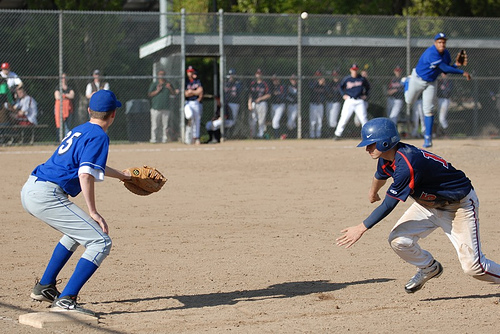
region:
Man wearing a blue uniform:
[19, 85, 167, 317]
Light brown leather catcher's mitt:
[122, 163, 165, 198]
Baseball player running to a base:
[331, 112, 498, 294]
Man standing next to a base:
[17, 87, 168, 314]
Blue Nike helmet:
[354, 115, 401, 152]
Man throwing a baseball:
[399, 32, 473, 147]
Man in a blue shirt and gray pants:
[402, 30, 472, 149]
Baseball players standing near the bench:
[178, 55, 411, 142]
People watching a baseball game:
[0, 58, 176, 141]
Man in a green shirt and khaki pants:
[145, 68, 177, 145]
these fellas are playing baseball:
[32, 0, 494, 330]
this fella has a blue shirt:
[13, 75, 195, 314]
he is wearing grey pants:
[12, 171, 134, 275]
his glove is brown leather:
[128, 157, 165, 193]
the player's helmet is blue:
[347, 105, 407, 165]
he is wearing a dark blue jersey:
[383, 136, 470, 214]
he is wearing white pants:
[398, 188, 494, 287]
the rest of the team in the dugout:
[173, 63, 353, 133]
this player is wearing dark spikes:
[25, 280, 107, 316]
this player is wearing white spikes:
[395, 260, 454, 292]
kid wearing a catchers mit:
[115, 145, 164, 221]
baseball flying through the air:
[269, 10, 359, 45]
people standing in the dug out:
[173, 65, 335, 114]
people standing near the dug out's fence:
[198, 72, 317, 141]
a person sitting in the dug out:
[208, 82, 237, 143]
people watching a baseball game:
[4, 67, 46, 146]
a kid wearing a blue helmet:
[353, 113, 390, 152]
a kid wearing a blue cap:
[67, 91, 129, 118]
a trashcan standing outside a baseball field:
[125, 94, 151, 139]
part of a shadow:
[309, 298, 313, 310]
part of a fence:
[255, 118, 259, 128]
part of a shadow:
[300, 286, 305, 294]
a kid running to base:
[360, 100, 481, 291]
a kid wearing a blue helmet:
[361, 117, 396, 160]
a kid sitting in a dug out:
[211, 96, 234, 144]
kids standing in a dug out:
[245, 53, 317, 128]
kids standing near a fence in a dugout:
[234, 55, 295, 132]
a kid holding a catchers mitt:
[116, 149, 159, 211]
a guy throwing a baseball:
[416, 34, 490, 104]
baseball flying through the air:
[274, 11, 343, 36]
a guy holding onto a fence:
[142, 67, 176, 121]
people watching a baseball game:
[5, 72, 110, 83]